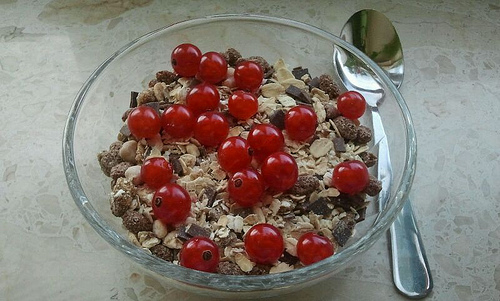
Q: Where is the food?
A: In a bowl.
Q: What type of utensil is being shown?
A: A spoon.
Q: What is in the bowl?
A: Cereal.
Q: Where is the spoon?
A: On the counter.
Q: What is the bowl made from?
A: Glass.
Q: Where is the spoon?
A: On side the bowl.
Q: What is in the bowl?
A: Red fruits.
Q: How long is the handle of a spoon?
A: Long.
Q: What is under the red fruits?
A: Oats.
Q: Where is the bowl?
A: Over the table.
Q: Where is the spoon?
A: On the table.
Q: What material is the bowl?
A: Glass.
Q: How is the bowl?
A: Round.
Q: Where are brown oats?
A: In the bowl.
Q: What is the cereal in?
A: Bowl.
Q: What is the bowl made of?
A: Glass.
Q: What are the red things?
A: Cranberries.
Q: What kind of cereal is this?
A: Granola.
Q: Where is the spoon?
A: Next to the bowl.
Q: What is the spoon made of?
A: Metal.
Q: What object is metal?
A: Spoon.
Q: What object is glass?
A: Bowl.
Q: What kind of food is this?
A: Breakfast cereal.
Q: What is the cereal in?
A: Bowl.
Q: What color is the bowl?
A: Clear.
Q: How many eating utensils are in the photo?
A: One.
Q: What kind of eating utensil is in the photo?
A: Spoon.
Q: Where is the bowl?
A: Table.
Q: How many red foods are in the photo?
A: One.